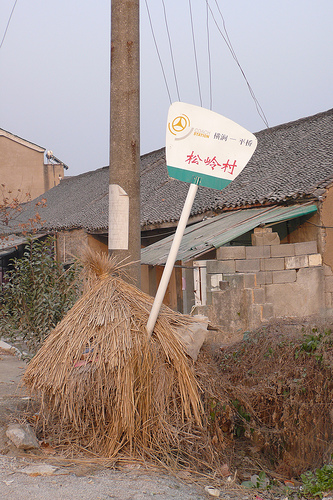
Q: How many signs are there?
A: One.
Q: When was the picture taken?
A: Daytime.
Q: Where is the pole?
A: Behind the straw.